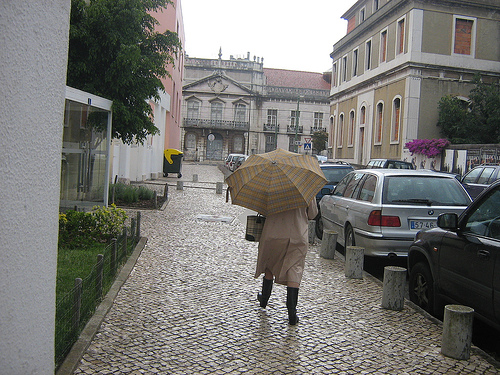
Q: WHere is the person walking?
A: On the sidewalk.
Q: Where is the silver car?
A: Parked on the street.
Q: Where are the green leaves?
A: On the trees.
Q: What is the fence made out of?
A: Metal and wood.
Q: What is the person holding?
A: An umbrella.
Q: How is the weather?
A: The weather is rainy.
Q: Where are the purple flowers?
A: Overhanging a fence.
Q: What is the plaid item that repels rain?
A: Umbrella.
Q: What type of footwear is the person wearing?
A: Boots.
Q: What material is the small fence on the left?
A: Wire.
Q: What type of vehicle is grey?
A: Car.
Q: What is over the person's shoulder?
A: Umbrella.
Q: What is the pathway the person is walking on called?
A: Sidewalk.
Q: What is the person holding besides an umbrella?
A: Purse.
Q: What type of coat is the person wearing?
A: Rain.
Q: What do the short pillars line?
A: Curb.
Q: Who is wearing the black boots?
A: The woman.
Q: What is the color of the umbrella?
A: Brown.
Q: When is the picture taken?
A: Daytime.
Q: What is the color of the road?
A: Grey.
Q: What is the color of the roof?
A: Red.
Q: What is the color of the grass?
A: Green.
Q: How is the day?
A: Cloudy.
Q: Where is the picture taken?
A: On a sidewalk, outside.